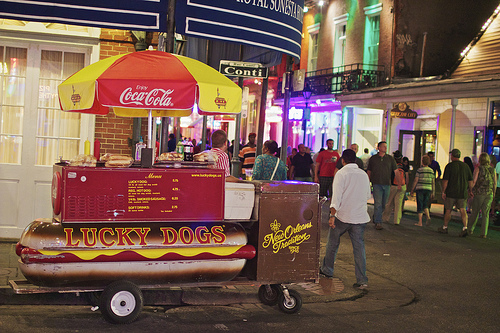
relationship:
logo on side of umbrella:
[113, 76, 184, 116] [52, 42, 243, 124]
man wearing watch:
[311, 147, 379, 291] [326, 212, 337, 219]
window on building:
[360, 10, 384, 75] [300, 1, 467, 84]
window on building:
[0, 44, 24, 162] [0, 0, 305, 245]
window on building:
[31, 49, 81, 166] [0, 0, 305, 245]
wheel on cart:
[101, 285, 147, 325] [10, 42, 328, 317]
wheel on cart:
[257, 282, 303, 317] [10, 42, 328, 317]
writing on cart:
[57, 223, 233, 249] [18, 154, 325, 316]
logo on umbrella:
[116, 82, 179, 113] [58, 49, 245, 119]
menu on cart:
[64, 163, 209, 238] [16, 53, 326, 303]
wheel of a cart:
[101, 285, 147, 325] [10, 42, 328, 317]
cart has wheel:
[10, 42, 328, 317] [98, 280, 147, 326]